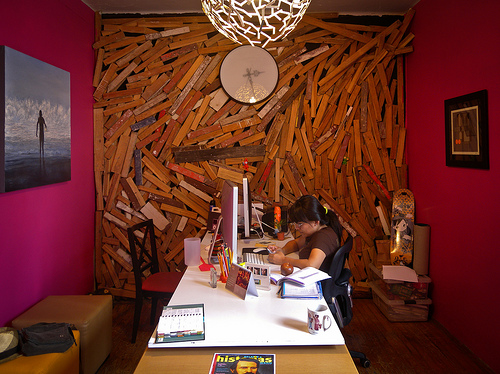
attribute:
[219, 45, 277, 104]
clock — numberless, white, round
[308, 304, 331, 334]
coffee mug — ceramic, white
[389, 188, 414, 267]
skateboard — in the corner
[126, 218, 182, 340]
chair — red, black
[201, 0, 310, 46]
light fixture — modernistic, modern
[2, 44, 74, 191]
photo — an ocean scene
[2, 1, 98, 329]
wall — covered in boards, purple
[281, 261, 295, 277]
apple — red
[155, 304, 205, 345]
appointment book — open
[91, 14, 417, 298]
wall — artistic, planks of wood, strips of wood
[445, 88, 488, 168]
artwork — framed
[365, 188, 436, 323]
clutter — piled up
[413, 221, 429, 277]
cardboard tube — brown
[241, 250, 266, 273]
keyboard — white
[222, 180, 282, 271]
desktop computer — apple brand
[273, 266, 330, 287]
notebook — open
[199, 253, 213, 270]
flyswatter — red